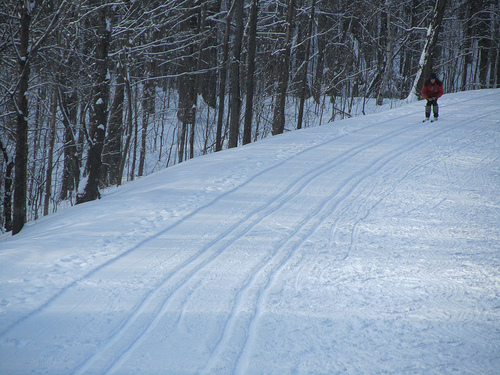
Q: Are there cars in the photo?
A: No, there are no cars.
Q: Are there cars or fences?
A: No, there are no cars or fences.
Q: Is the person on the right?
A: Yes, the person is on the right of the image.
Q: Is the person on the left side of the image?
A: No, the person is on the right of the image.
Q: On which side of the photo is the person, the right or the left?
A: The person is on the right of the image.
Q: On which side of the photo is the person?
A: The person is on the right of the image.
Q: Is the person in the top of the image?
A: Yes, the person is in the top of the image.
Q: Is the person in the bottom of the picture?
A: No, the person is in the top of the image.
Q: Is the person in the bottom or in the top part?
A: The person is in the top of the image.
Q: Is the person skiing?
A: Yes, the person is skiing.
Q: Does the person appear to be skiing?
A: Yes, the person is skiing.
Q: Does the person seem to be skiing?
A: Yes, the person is skiing.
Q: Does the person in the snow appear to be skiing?
A: Yes, the person is skiing.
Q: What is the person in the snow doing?
A: The person is skiing.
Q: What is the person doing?
A: The person is skiing.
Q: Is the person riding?
A: No, the person is skiing.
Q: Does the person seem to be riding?
A: No, the person is skiing.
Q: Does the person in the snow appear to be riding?
A: No, the person is skiing.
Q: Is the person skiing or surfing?
A: The person is skiing.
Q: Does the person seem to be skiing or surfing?
A: The person is skiing.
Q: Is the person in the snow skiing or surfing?
A: The person is skiing.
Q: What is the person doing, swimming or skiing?
A: The person is skiing.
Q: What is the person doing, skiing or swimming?
A: The person is skiing.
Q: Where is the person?
A: The person is in the snow.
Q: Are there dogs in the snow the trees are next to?
A: No, there is a person in the snow.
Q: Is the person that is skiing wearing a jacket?
A: Yes, the person is wearing a jacket.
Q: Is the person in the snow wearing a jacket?
A: Yes, the person is wearing a jacket.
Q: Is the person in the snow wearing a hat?
A: Yes, the person is wearing a hat.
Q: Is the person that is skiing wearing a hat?
A: Yes, the person is wearing a hat.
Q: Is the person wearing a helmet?
A: No, the person is wearing a hat.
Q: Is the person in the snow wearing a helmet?
A: No, the person is wearing a hat.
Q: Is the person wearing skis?
A: Yes, the person is wearing skis.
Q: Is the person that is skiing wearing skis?
A: Yes, the person is wearing skis.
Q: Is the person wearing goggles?
A: No, the person is wearing skis.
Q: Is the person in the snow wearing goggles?
A: No, the person is wearing skis.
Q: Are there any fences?
A: No, there are no fences.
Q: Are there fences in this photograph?
A: No, there are no fences.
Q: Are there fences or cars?
A: No, there are no fences or cars.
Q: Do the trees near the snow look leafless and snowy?
A: Yes, the trees are leafless and snowy.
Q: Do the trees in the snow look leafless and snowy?
A: Yes, the trees are leafless and snowy.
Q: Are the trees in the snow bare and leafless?
A: No, the trees are leafless but snowy.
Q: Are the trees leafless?
A: Yes, the trees are leafless.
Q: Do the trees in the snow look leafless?
A: Yes, the trees are leafless.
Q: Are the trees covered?
A: No, the trees are leafless.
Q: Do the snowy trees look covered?
A: No, the trees are leafless.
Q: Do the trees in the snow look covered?
A: No, the trees are leafless.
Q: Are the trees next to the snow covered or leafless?
A: The trees are leafless.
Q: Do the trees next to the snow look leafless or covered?
A: The trees are leafless.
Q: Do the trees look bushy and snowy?
A: No, the trees are snowy but leafless.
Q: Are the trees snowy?
A: Yes, the trees are snowy.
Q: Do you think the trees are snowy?
A: Yes, the trees are snowy.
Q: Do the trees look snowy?
A: Yes, the trees are snowy.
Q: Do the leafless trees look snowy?
A: Yes, the trees are snowy.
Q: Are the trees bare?
A: No, the trees are snowy.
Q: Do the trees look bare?
A: No, the trees are snowy.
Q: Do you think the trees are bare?
A: No, the trees are snowy.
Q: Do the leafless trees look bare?
A: No, the trees are snowy.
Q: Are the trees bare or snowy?
A: The trees are snowy.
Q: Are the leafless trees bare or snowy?
A: The trees are snowy.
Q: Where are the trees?
A: The trees are in the snow.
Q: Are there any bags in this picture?
A: No, there are no bags.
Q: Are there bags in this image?
A: No, there are no bags.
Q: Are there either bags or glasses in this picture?
A: No, there are no bags or glasses.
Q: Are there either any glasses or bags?
A: No, there are no bags or glasses.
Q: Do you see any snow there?
A: Yes, there is snow.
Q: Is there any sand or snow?
A: Yes, there is snow.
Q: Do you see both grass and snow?
A: No, there is snow but no grass.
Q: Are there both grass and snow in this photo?
A: No, there is snow but no grass.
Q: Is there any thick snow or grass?
A: Yes, there is thick snow.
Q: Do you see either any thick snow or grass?
A: Yes, there is thick snow.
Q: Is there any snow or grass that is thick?
A: Yes, the snow is thick.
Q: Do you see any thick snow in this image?
A: Yes, there is thick snow.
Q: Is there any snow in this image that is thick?
A: Yes, there is snow that is thick.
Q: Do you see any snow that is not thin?
A: Yes, there is thick snow.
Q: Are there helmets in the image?
A: No, there are no helmets.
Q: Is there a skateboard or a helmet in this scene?
A: No, there are no helmets or skateboards.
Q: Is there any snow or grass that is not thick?
A: No, there is snow but it is thick.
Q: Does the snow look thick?
A: Yes, the snow is thick.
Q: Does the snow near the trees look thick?
A: Yes, the snow is thick.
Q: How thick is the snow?
A: The snow is thick.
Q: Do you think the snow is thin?
A: No, the snow is thick.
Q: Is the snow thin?
A: No, the snow is thick.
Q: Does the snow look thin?
A: No, the snow is thick.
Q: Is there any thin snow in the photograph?
A: No, there is snow but it is thick.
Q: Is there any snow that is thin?
A: No, there is snow but it is thick.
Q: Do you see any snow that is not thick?
A: No, there is snow but it is thick.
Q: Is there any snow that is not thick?
A: No, there is snow but it is thick.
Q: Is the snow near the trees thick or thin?
A: The snow is thick.